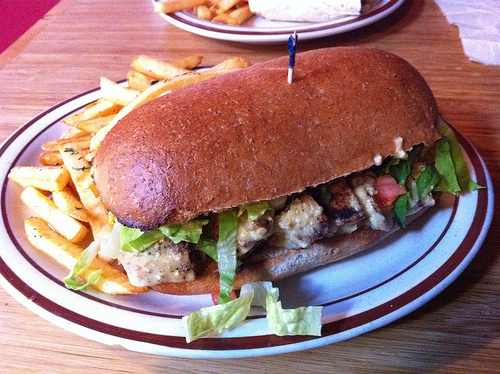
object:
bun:
[92, 47, 443, 229]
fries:
[25, 213, 149, 293]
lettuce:
[180, 281, 324, 344]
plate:
[0, 65, 494, 358]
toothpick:
[287, 30, 298, 84]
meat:
[120, 237, 195, 286]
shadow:
[105, 123, 498, 373]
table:
[0, 0, 499, 373]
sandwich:
[92, 45, 459, 294]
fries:
[225, 5, 253, 26]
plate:
[153, 0, 406, 44]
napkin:
[433, 0, 499, 67]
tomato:
[376, 175, 407, 212]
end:
[287, 37, 298, 69]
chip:
[112, 342, 129, 351]